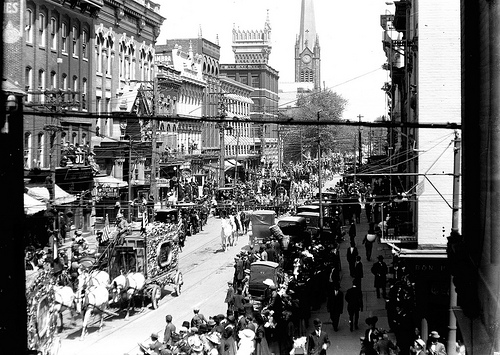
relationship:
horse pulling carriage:
[69, 247, 154, 348] [104, 216, 185, 304]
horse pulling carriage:
[69, 281, 111, 343] [100, 220, 182, 309]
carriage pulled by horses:
[110, 223, 179, 285] [44, 279, 111, 319]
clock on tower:
[302, 54, 309, 62] [295, 0, 321, 92]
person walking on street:
[345, 240, 358, 267] [9, 162, 357, 353]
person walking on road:
[221, 280, 233, 314] [24, 169, 343, 354]